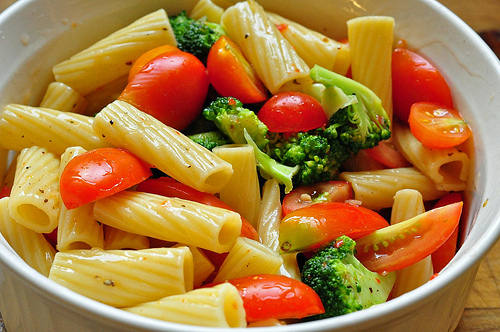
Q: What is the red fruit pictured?
A: Tomatoes.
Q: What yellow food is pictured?
A: Noodles.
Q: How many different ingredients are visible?
A: Three.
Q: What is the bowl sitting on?
A: Table.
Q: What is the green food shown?
A: Broccoli.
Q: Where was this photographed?
A: At a table.